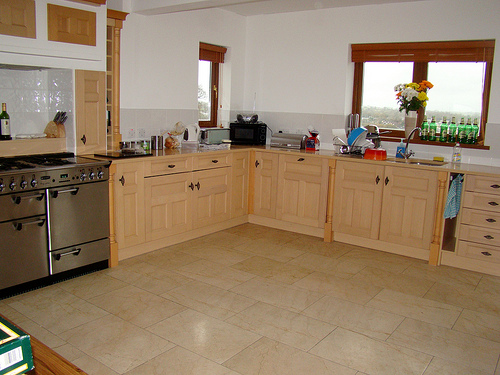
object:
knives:
[43, 111, 68, 138]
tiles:
[0, 65, 76, 155]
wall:
[119, 26, 198, 122]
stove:
[3, 155, 109, 272]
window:
[348, 39, 491, 150]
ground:
[379, 160, 436, 213]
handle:
[481, 252, 491, 256]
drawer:
[457, 240, 500, 265]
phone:
[218, 255, 368, 356]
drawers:
[144, 152, 231, 177]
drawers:
[454, 175, 499, 266]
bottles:
[420, 116, 477, 144]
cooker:
[0, 151, 109, 291]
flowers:
[394, 80, 434, 115]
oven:
[0, 151, 111, 291]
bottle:
[0, 103, 12, 140]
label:
[1, 119, 10, 135]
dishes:
[333, 125, 387, 160]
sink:
[391, 125, 444, 169]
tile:
[308, 325, 434, 374]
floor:
[0, 221, 499, 373]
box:
[0, 318, 34, 375]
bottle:
[452, 141, 462, 170]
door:
[333, 159, 384, 242]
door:
[379, 164, 441, 250]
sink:
[384, 124, 444, 166]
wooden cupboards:
[110, 142, 499, 277]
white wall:
[236, 12, 353, 122]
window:
[197, 57, 212, 121]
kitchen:
[0, 1, 498, 375]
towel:
[443, 173, 463, 219]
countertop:
[79, 145, 495, 177]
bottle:
[472, 118, 479, 144]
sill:
[351, 127, 484, 147]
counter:
[239, 145, 500, 176]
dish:
[433, 156, 444, 162]